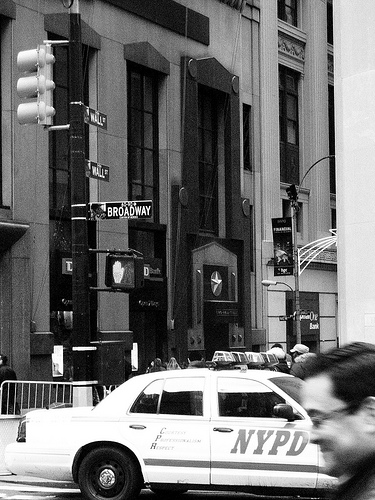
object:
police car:
[4, 350, 338, 500]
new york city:
[1, 0, 374, 497]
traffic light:
[13, 40, 57, 127]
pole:
[68, 0, 89, 407]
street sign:
[87, 191, 155, 225]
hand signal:
[112, 261, 127, 286]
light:
[104, 258, 138, 292]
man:
[289, 342, 375, 500]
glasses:
[306, 404, 346, 427]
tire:
[78, 447, 138, 499]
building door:
[186, 233, 245, 351]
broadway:
[103, 202, 150, 218]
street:
[0, 458, 332, 500]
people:
[166, 358, 182, 371]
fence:
[1, 380, 72, 418]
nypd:
[228, 429, 310, 454]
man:
[287, 342, 311, 364]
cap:
[289, 341, 310, 353]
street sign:
[88, 162, 113, 180]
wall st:
[91, 162, 113, 180]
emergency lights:
[210, 349, 250, 371]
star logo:
[208, 267, 223, 299]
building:
[0, 0, 335, 408]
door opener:
[210, 426, 234, 434]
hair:
[290, 341, 375, 417]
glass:
[217, 376, 287, 416]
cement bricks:
[96, 35, 127, 139]